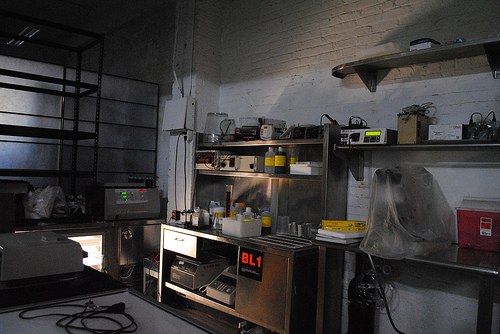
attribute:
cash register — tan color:
[203, 262, 240, 302]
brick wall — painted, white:
[241, 10, 331, 97]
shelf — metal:
[258, 132, 318, 147]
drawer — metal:
[155, 217, 204, 262]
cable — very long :
[17, 291, 141, 330]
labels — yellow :
[257, 137, 299, 197]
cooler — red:
[453, 198, 498, 250]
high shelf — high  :
[331, 32, 499, 94]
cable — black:
[19, 297, 139, 332]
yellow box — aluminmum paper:
[321, 218, 366, 234]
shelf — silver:
[328, 32, 498, 93]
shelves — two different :
[326, 32, 498, 182]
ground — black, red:
[278, 35, 316, 67]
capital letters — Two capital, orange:
[238, 251, 255, 266]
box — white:
[161, 96, 193, 133]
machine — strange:
[99, 175, 155, 227]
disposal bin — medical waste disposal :
[451, 197, 497, 255]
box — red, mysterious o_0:
[445, 182, 499, 249]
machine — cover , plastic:
[109, 76, 468, 306]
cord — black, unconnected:
[68, 293, 142, 330]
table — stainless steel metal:
[371, 246, 478, 288]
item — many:
[224, 216, 259, 237]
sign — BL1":
[234, 247, 274, 274]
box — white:
[266, 171, 306, 190]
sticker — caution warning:
[477, 214, 495, 237]